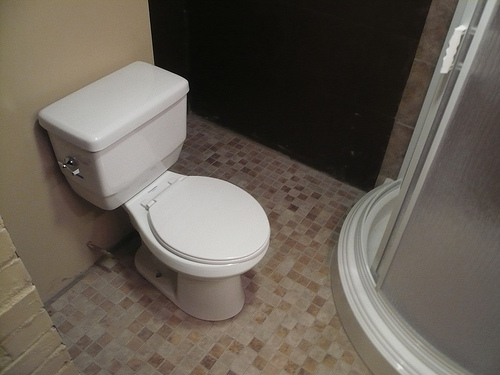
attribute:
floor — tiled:
[250, 140, 311, 205]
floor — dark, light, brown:
[231, 161, 431, 293]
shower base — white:
[330, 177, 465, 374]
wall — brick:
[0, 219, 76, 374]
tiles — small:
[186, 149, 391, 374]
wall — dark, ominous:
[146, 0, 429, 197]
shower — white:
[321, 42, 493, 300]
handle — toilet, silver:
[52, 153, 87, 182]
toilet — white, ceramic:
[117, 159, 289, 334]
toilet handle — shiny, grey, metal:
[56, 157, 81, 179]